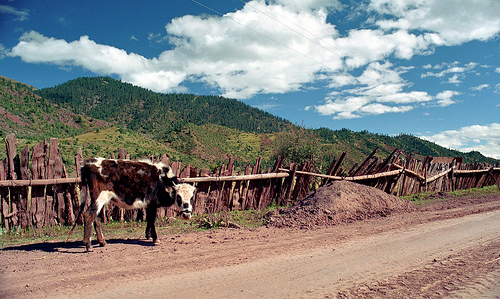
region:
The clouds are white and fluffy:
[200, 14, 323, 74]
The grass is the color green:
[73, 75, 268, 145]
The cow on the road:
[57, 150, 202, 251]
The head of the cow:
[165, 171, 200, 221]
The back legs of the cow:
[80, 200, 106, 246]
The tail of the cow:
[61, 165, 91, 245]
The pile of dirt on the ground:
[251, 174, 409, 233]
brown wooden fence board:
[4, 131, 41, 226]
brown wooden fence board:
[20, 140, 35, 190]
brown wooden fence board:
[32, 143, 49, 181]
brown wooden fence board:
[48, 132, 65, 177]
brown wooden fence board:
[69, 153, 82, 179]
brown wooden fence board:
[171, 157, 183, 178]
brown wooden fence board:
[212, 160, 229, 203]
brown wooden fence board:
[243, 167, 255, 201]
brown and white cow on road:
[61, 149, 200, 258]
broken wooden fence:
[5, 130, 499, 239]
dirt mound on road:
[283, 172, 413, 227]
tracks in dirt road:
[325, 245, 495, 297]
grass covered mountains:
[3, 69, 495, 172]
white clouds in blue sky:
[313, 44, 469, 126]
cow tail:
[67, 171, 91, 238]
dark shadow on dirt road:
[3, 229, 156, 266]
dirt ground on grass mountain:
[50, 106, 110, 132]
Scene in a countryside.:
[1, 0, 491, 291]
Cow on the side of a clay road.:
[60, 145, 200, 250]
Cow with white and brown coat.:
[70, 155, 200, 255]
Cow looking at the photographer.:
[165, 175, 200, 220]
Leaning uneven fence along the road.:
[200, 150, 490, 215]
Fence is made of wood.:
[200, 150, 490, 200]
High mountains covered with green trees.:
[1, 75, 481, 150]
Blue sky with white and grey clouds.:
[0, 5, 490, 80]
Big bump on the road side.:
[255, 180, 405, 235]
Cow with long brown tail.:
[61, 174, 94, 250]